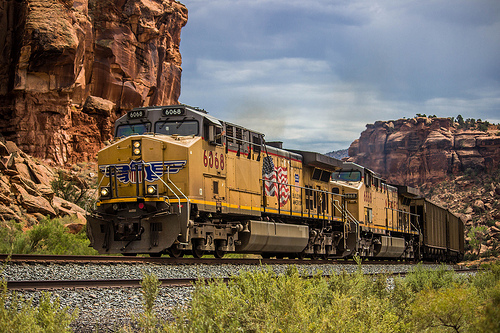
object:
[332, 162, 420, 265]
train car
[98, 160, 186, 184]
eagle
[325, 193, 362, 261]
steps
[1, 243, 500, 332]
railroad tracks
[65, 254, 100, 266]
railway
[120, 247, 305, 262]
wheels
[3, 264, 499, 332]
bush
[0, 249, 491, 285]
tracks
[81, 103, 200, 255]
front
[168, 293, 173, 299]
rocks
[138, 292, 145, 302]
rocks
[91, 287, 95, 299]
rocks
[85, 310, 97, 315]
rocks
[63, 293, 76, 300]
rocks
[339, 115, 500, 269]
rock formation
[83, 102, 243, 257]
engine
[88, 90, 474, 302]
train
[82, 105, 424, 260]
yellow train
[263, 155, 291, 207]
flag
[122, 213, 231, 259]
wheels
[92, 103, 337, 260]
train car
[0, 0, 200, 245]
rock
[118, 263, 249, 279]
gravel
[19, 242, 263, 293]
tracks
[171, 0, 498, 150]
sky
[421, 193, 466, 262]
car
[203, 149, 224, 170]
number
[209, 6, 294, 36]
clouds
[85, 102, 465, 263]
train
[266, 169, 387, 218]
side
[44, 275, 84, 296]
edge